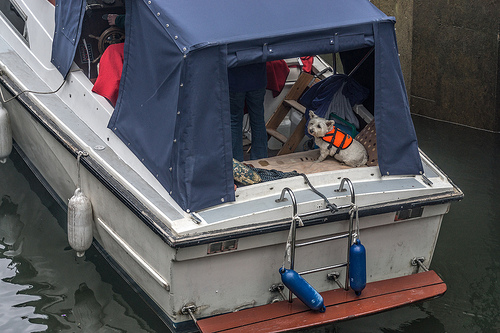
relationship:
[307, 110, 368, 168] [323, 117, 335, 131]
dog has ear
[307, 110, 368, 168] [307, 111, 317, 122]
dog has ear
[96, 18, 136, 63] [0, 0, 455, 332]
navigation wheel on boat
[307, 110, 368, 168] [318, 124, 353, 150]
dog wearing life vest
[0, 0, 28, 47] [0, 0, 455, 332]
glass on boat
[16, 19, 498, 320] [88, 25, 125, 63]
boat has navigation wheel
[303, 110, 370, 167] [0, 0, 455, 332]
dog inside boat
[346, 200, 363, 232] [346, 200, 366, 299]
rope on buoy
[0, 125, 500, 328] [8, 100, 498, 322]
reflections on water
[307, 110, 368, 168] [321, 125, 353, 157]
dog wearing jacket